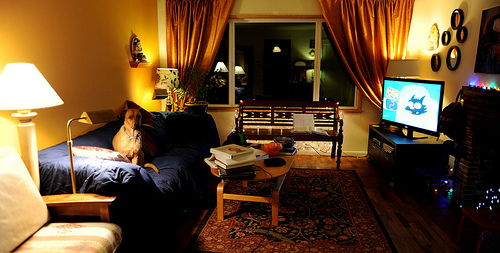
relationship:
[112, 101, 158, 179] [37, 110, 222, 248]
dog on blue couch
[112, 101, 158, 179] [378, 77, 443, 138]
dog near television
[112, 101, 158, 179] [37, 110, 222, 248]
dog sitting on blue couch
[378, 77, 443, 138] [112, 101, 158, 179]
television near dog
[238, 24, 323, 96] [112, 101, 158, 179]
window near dog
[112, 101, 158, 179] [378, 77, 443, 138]
dog by television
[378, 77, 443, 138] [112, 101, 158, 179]
television by dog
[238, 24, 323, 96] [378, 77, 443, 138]
window by television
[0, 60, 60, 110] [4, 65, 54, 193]
shade on lamp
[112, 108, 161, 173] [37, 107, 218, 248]
dog on blue couch